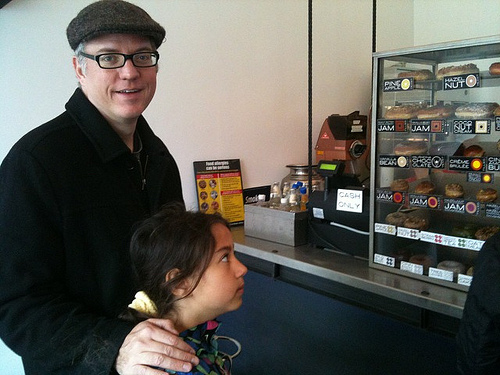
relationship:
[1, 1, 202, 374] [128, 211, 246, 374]
man next to a girl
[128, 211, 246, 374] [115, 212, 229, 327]
girl has hair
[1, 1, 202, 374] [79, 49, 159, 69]
man has on glasses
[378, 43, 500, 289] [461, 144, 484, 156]
display case has a pastry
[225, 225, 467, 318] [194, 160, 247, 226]
counter top has a sign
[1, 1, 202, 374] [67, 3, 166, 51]
man wearing a hat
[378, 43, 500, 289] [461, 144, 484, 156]
display case has pastry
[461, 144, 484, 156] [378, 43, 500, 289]
pastry are in display case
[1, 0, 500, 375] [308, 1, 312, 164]
wall has a line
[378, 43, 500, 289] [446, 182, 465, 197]
display case has donuts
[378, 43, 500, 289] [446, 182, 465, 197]
display case has a donuts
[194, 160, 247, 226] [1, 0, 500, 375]
sign against wall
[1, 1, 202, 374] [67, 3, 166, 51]
man has on a hat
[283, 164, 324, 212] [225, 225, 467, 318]
glass jar on counter top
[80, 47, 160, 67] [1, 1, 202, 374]
eyeglasses are on a man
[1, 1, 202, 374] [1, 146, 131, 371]
man has an arm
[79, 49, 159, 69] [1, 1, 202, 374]
glasses are on a man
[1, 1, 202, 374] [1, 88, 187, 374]
man wearing a jacket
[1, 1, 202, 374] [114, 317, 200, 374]
man has a hand